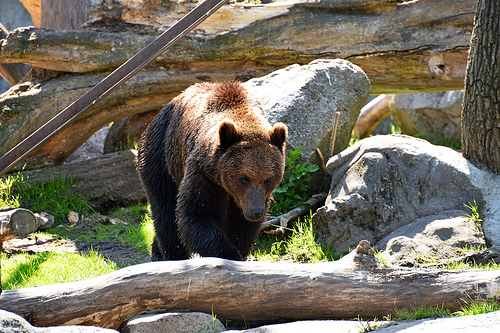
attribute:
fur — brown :
[196, 65, 259, 120]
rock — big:
[312, 132, 499, 260]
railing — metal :
[0, 0, 229, 175]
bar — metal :
[0, 0, 227, 179]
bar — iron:
[8, 10, 188, 119]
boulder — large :
[308, 126, 498, 277]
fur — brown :
[148, 97, 210, 159]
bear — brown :
[165, 71, 309, 256]